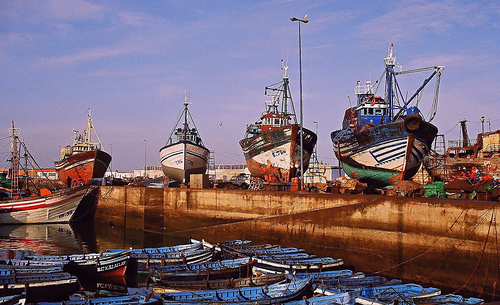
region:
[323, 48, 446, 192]
The large blue and white ship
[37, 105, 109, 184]
The large ship that is mostly red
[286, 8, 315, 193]
The street light on the dock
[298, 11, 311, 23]
The bird on top of the street light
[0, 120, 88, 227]
The large white and red line in the water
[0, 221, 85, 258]
The reflection of the white and red ship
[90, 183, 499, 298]
The large concrete wall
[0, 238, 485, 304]
The group of small boats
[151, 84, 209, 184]
The large white and grey boat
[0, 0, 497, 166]
The clouds in the sky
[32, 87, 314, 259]
the boats are docked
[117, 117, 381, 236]
the boats are docked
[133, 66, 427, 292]
the boats are docked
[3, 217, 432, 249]
a body of water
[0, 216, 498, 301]
many fishing boats in a body of water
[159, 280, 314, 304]
a white fishing boat in water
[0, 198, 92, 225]
a white and red fishing boat in water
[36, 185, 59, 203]
a red buoy on top of fishing boat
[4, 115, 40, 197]
a tall mask on fishing boat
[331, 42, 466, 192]
a white and blue boat in dry dock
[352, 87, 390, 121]
a blue cabin on fishing boat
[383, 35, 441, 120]
a tall mask on fishing boat in dry dock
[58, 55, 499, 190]
Many fishing boats are in dry dock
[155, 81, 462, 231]
boats docked in port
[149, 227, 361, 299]
smaller boats in the water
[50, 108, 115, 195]
red boat on the left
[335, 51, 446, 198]
blue boat on the right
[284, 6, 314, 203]
lightpole above boats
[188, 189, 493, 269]
largew concrete seawall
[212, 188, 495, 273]
seawall is gray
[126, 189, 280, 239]
seawall has rust stains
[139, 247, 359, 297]
small boats are white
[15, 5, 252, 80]
blue sky with some clouds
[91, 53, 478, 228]
boats out of the water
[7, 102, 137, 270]
boat in the water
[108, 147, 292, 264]
a cement wall against water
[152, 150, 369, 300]
a tall cement wall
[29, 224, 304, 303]
empty boats on water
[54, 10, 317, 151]
a blue sky with clouds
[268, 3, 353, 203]
a tall light pole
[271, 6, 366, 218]
a tall metal pole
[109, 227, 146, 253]
a body of water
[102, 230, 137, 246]
a body of dirty water